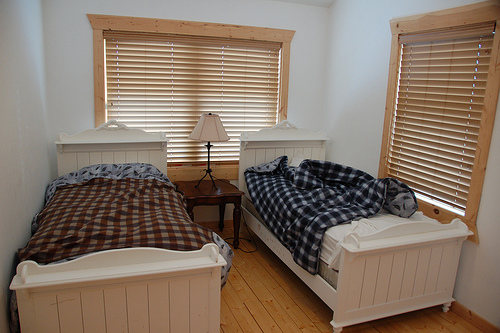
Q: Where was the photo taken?
A: A bedroom.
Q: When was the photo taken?
A: During the day.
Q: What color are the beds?
A: White.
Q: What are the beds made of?
A: Wood.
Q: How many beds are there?
A: Two.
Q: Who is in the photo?
A: No one.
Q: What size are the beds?
A: Twin.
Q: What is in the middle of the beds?
A: A table.